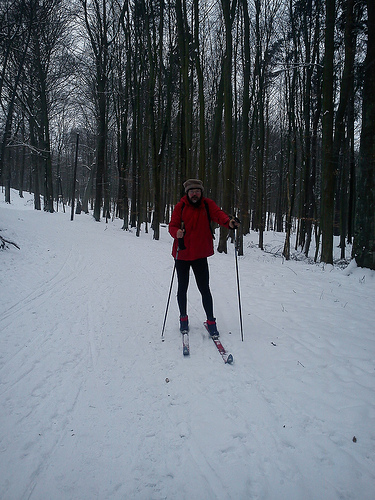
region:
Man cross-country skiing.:
[157, 177, 246, 365]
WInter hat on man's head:
[184, 176, 206, 192]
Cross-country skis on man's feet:
[179, 314, 234, 365]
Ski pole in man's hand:
[228, 218, 249, 342]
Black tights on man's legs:
[175, 257, 214, 322]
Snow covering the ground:
[0, 188, 373, 493]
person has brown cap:
[173, 179, 198, 191]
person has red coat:
[166, 190, 215, 261]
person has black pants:
[151, 259, 214, 331]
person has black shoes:
[173, 306, 233, 359]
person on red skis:
[159, 330, 232, 358]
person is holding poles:
[114, 212, 268, 369]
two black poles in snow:
[165, 212, 242, 355]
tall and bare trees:
[100, 4, 308, 221]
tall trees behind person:
[103, 20, 303, 220]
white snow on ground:
[73, 346, 160, 449]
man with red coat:
[157, 168, 247, 345]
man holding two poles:
[147, 166, 247, 343]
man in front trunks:
[0, 105, 361, 259]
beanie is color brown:
[171, 169, 221, 210]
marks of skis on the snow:
[10, 286, 109, 446]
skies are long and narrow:
[174, 309, 237, 368]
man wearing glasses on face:
[150, 168, 243, 263]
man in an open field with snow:
[14, 164, 374, 496]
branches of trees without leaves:
[5, 102, 103, 202]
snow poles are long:
[153, 206, 252, 347]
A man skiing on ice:
[149, 167, 264, 372]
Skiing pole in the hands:
[160, 266, 172, 336]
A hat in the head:
[180, 175, 206, 193]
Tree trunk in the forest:
[311, 152, 333, 238]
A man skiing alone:
[161, 165, 262, 351]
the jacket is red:
[163, 197, 226, 263]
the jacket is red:
[161, 195, 227, 257]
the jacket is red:
[167, 197, 238, 271]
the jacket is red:
[169, 199, 220, 252]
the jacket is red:
[168, 195, 219, 259]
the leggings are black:
[162, 259, 222, 322]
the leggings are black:
[171, 253, 226, 334]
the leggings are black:
[174, 253, 214, 319]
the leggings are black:
[174, 255, 219, 323]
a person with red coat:
[158, 167, 250, 348]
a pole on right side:
[227, 223, 255, 344]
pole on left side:
[155, 237, 187, 340]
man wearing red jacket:
[159, 177, 251, 366]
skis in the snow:
[174, 296, 236, 368]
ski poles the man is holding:
[144, 210, 250, 343]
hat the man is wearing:
[184, 176, 202, 187]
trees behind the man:
[2, 10, 371, 259]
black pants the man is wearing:
[171, 257, 218, 311]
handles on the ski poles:
[173, 211, 239, 241]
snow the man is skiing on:
[3, 183, 374, 496]